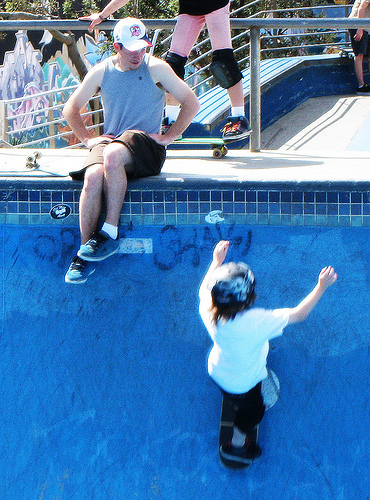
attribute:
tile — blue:
[229, 188, 370, 227]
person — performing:
[175, 227, 349, 482]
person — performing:
[48, 8, 204, 308]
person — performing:
[167, 2, 262, 158]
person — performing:
[340, 1, 368, 88]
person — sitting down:
[60, 14, 203, 286]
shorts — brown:
[66, 128, 168, 182]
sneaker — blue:
[57, 232, 138, 293]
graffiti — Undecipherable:
[31, 220, 252, 269]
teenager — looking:
[57, 15, 200, 282]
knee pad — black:
[210, 47, 243, 88]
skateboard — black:
[215, 394, 252, 473]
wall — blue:
[3, 187, 367, 498]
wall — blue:
[4, 251, 197, 384]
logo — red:
[126, 25, 143, 36]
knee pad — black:
[165, 51, 187, 81]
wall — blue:
[38, 90, 368, 279]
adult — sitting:
[53, 12, 204, 285]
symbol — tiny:
[137, 75, 142, 82]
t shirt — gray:
[99, 52, 167, 134]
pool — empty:
[3, 215, 351, 481]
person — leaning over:
[348, 0, 365, 94]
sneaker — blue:
[76, 229, 121, 262]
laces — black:
[69, 256, 85, 271]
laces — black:
[85, 229, 108, 249]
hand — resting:
[76, 13, 108, 37]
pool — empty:
[5, 177, 367, 498]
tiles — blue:
[0, 189, 368, 229]